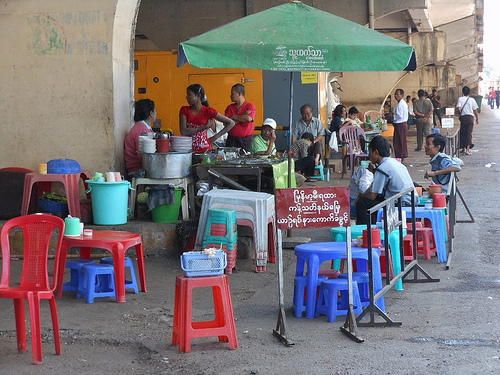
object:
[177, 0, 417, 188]
umbrella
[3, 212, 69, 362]
chair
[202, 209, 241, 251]
stools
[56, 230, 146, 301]
tables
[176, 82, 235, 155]
women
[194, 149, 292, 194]
table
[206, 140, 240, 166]
pot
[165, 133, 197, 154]
dishes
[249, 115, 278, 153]
man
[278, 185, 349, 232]
writing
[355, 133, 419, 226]
men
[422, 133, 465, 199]
people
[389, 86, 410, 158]
people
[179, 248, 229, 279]
basket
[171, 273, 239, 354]
stool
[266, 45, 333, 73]
writing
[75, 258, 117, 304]
chair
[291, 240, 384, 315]
table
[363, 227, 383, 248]
bucket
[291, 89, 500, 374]
sidewalk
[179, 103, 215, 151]
red shirts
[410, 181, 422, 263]
rails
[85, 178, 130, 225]
bucket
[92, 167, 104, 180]
rags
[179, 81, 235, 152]
woman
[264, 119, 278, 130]
cap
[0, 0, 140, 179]
wall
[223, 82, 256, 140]
man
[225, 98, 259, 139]
shirt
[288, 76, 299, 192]
pole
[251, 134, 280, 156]
shirt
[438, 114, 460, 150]
post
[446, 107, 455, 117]
signs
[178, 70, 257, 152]
woman and man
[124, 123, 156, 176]
red shirts